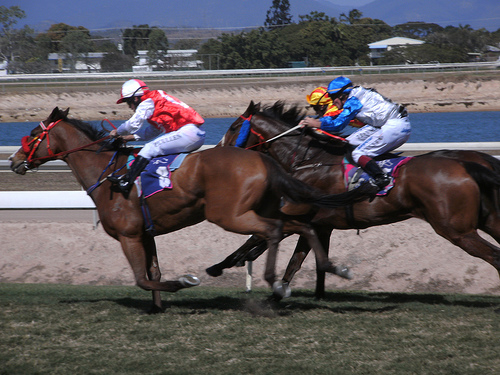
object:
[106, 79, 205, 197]
man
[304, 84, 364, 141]
man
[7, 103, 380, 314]
horse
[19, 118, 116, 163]
briddles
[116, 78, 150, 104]
helmet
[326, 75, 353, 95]
helmet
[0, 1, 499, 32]
sky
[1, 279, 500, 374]
grass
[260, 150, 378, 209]
tail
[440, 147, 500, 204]
tail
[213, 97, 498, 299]
horse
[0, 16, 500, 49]
power lines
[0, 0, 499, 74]
trees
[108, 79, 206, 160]
red and white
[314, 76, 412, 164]
blue and white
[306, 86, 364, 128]
red and gold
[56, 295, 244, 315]
shadow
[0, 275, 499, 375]
ground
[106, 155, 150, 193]
boots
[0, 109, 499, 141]
water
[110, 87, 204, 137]
shirt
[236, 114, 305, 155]
briddles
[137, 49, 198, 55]
roof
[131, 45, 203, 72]
house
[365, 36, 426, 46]
roof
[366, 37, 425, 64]
house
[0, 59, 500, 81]
guard rail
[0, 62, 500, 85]
road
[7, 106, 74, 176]
head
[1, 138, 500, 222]
fence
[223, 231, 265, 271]
leg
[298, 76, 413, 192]
man